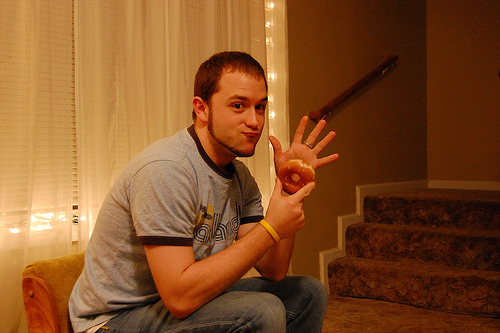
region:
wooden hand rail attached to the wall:
[303, 18, 431, 138]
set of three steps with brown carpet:
[333, 163, 494, 313]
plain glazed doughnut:
[276, 149, 333, 202]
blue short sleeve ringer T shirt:
[81, 112, 288, 332]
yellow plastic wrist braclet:
[246, 207, 292, 257]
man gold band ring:
[296, 128, 331, 156]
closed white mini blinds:
[41, 16, 92, 236]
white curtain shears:
[25, 10, 189, 259]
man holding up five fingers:
[265, 106, 355, 198]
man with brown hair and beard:
[173, 37, 279, 161]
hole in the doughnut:
[283, 171, 304, 186]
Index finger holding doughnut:
[284, 174, 317, 209]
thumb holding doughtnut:
[262, 173, 286, 212]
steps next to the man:
[387, 153, 485, 315]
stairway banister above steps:
[295, 34, 410, 147]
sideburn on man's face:
[201, 97, 220, 176]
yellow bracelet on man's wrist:
[255, 213, 275, 253]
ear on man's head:
[186, 95, 213, 127]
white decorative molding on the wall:
[301, 172, 431, 262]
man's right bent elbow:
[155, 290, 195, 327]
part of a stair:
[438, 226, 445, 231]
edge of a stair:
[401, 207, 415, 224]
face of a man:
[230, 82, 262, 169]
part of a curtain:
[88, 104, 126, 184]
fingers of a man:
[311, 133, 327, 148]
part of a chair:
[46, 271, 73, 311]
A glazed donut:
[269, 151, 323, 196]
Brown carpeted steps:
[321, 177, 498, 304]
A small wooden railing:
[307, 45, 407, 128]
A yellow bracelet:
[247, 207, 294, 250]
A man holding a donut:
[60, 47, 363, 330]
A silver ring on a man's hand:
[300, 133, 317, 153]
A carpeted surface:
[338, 300, 413, 331]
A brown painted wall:
[430, 42, 489, 176]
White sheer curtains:
[16, 65, 71, 252]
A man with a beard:
[174, 44, 274, 171]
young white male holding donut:
[111, 37, 343, 224]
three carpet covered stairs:
[326, 170, 482, 332]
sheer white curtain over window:
[10, 10, 134, 223]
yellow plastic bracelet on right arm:
[252, 209, 287, 250]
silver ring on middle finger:
[299, 139, 318, 150]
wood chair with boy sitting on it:
[21, 252, 123, 324]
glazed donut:
[271, 154, 318, 194]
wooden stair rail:
[292, 35, 404, 135]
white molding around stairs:
[303, 171, 493, 288]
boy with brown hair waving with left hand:
[185, 49, 347, 213]